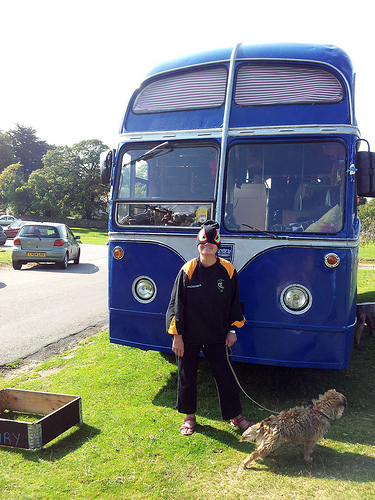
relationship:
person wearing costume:
[165, 223, 247, 438] [198, 222, 221, 257]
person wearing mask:
[165, 223, 247, 438] [198, 222, 221, 257]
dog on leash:
[241, 388, 348, 471] [224, 348, 277, 414]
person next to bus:
[165, 223, 247, 438] [106, 38, 374, 372]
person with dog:
[165, 223, 247, 438] [241, 388, 348, 471]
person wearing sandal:
[165, 223, 247, 438] [181, 416, 194, 439]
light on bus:
[281, 284, 308, 314] [106, 38, 374, 372]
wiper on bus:
[125, 144, 173, 172] [106, 38, 374, 372]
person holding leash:
[165, 223, 247, 438] [224, 348, 277, 414]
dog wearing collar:
[241, 388, 348, 471] [309, 407, 332, 422]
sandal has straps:
[181, 416, 194, 439] [181, 418, 199, 431]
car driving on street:
[13, 220, 81, 271] [0, 242, 111, 365]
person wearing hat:
[165, 223, 247, 438] [197, 220, 222, 250]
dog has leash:
[241, 388, 348, 471] [224, 348, 277, 414]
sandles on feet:
[181, 420, 253, 437] [179, 422, 249, 438]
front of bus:
[115, 64, 346, 368] [106, 38, 374, 372]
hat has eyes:
[197, 222, 220, 249] [201, 231, 220, 243]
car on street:
[13, 220, 81, 271] [0, 242, 111, 365]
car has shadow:
[13, 220, 81, 271] [31, 262, 98, 276]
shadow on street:
[31, 262, 98, 276] [0, 242, 111, 365]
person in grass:
[165, 223, 247, 438] [1, 228, 374, 499]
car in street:
[13, 220, 81, 271] [0, 242, 111, 365]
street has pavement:
[0, 242, 111, 365] [0, 245, 111, 369]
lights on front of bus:
[129, 277, 313, 317] [106, 38, 374, 372]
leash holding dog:
[224, 348, 277, 414] [241, 388, 348, 471]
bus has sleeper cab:
[106, 38, 374, 372] [125, 44, 353, 126]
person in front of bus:
[165, 223, 247, 438] [106, 38, 374, 372]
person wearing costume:
[165, 223, 247, 438] [165, 219, 245, 421]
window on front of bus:
[118, 144, 218, 232] [106, 38, 374, 372]